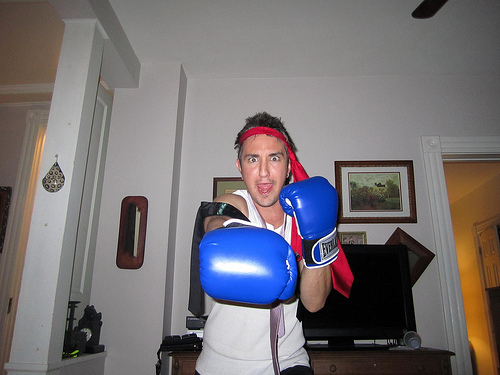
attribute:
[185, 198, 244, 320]
tie — black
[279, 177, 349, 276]
glove — boxing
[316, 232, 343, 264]
letters — black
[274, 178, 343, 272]
glove — blue, boxing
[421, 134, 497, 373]
frame — white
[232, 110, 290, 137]
hair — disheveled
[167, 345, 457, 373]
table — wood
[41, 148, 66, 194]
item — decorative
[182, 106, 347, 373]
man — blue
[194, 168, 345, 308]
gloves — large  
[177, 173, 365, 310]
gloves — Blue 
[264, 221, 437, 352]
television — black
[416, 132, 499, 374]
doorway — white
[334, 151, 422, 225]
picture — rectangle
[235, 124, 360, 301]
tie — bright , red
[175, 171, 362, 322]
gear — boxing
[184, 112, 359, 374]
man — standing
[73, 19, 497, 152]
wall — Sandy 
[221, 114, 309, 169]
tie — red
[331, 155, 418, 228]
picture — brown, framed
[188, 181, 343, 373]
tank top — white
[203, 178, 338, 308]
boxing gloves — blue, white, black